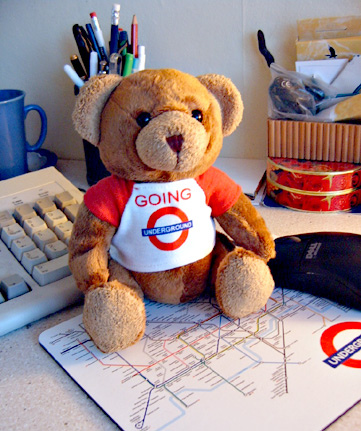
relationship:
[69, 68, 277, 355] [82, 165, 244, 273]
bear wearing shirt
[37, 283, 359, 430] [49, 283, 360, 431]
mouse pad has map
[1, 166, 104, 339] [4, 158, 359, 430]
keyboard on top of desk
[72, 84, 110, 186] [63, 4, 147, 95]
cup holding pens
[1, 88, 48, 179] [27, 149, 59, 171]
cup on plate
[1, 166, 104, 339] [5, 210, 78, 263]
keyboard has numbers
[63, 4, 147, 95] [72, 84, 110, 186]
pens in cup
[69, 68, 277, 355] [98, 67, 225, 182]
bear has face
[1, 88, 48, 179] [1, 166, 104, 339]
cup next to keyboard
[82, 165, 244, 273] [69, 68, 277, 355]
shirt on bear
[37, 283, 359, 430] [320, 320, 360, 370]
mouse pad has logo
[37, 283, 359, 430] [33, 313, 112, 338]
mouse pad has edge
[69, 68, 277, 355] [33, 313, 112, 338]
bear on edge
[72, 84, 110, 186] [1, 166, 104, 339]
cup behind keyboard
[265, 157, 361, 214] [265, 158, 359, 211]
can has roses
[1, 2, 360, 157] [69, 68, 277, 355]
wall behind bear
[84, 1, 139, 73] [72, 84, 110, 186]
pencils in cup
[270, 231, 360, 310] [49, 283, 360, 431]
mouse beside map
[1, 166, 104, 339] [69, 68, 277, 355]
keyboard behind bear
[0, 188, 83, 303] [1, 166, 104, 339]
keys on keyboard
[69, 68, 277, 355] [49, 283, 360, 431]
bear on map